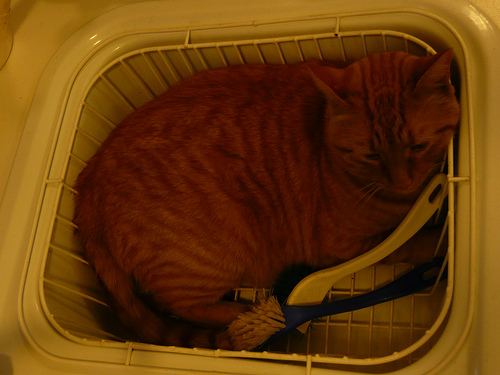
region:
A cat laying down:
[47, 35, 472, 336]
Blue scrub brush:
[206, 255, 456, 355]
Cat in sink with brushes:
[35, 32, 481, 370]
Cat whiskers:
[340, 147, 406, 227]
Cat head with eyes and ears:
[295, 33, 470, 218]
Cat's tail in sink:
[48, 205, 278, 356]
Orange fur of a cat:
[140, 120, 246, 232]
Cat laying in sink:
[20, 25, 467, 372]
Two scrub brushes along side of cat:
[206, 155, 464, 351]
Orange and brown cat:
[62, 22, 456, 246]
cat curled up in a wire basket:
[45, 28, 482, 369]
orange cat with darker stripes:
[77, 30, 462, 320]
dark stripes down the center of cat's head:
[355, 50, 421, 190]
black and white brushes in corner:
[190, 170, 465, 365]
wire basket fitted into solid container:
[25, 20, 471, 366]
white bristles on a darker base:
[220, 275, 348, 353]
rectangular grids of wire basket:
[320, 260, 430, 360]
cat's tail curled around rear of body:
[62, 157, 277, 362]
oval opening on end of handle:
[366, 167, 466, 254]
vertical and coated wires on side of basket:
[65, 23, 317, 99]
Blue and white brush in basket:
[230, 309, 423, 342]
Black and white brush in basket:
[279, 277, 376, 306]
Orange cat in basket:
[43, 37, 455, 337]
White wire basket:
[14, 22, 488, 362]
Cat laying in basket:
[51, 43, 478, 355]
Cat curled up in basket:
[82, 29, 490, 374]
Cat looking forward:
[298, 37, 462, 206]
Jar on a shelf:
[0, 14, 17, 63]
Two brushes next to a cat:
[161, 146, 458, 356]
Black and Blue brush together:
[221, 248, 425, 373]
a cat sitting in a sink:
[13, 23, 470, 370]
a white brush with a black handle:
[228, 259, 483, 351]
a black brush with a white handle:
[270, 167, 448, 344]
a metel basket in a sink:
[36, 20, 471, 373]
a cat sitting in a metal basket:
[48, 30, 465, 373]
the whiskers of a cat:
[337, 171, 396, 218]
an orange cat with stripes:
[85, 45, 452, 333]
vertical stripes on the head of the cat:
[353, 54, 422, 199]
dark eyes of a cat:
[348, 136, 446, 170]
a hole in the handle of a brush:
[419, 156, 462, 224]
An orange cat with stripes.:
[70, 41, 457, 334]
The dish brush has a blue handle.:
[225, 251, 445, 366]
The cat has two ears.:
[296, 42, 456, 98]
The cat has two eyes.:
[345, 130, 450, 165]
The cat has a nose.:
[385, 172, 420, 195]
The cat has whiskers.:
[345, 170, 390, 215]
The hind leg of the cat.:
[165, 275, 270, 327]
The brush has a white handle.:
[247, 156, 442, 339]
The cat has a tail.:
[46, 176, 238, 353]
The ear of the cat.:
[303, 51, 367, 123]